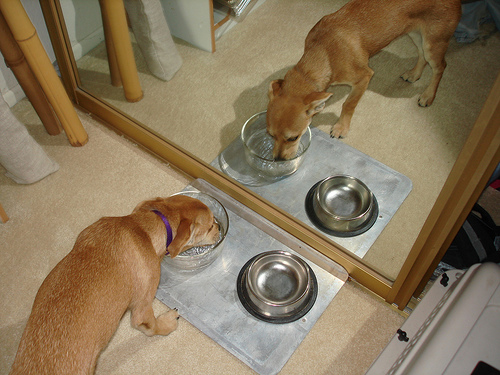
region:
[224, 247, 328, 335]
A metal water bowl with a rubber base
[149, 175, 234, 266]
A dog with his head in a glass bowl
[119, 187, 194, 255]
A purple collar around a dog's neck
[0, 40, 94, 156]
Bamboo propped in the corner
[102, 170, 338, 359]
A protective matt covering the carpet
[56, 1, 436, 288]
A large mirror against the wall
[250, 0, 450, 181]
The dog's reflection in the mirror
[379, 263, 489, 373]
A crate on the floor next to the mirror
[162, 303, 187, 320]
The dog's claws resting on the mat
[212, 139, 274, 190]
Light shining through the glass bowl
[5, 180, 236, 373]
a dog drinking water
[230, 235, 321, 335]
a silver food bowl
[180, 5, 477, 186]
the dog's reflection in the mirror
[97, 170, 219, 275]
the dog is wearing a purple collar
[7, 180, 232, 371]
the dog is brown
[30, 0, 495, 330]
the mirror's frame is brown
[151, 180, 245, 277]
the water bowl is clear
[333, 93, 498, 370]
the dog kennel is beside the mirror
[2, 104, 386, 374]
the carpet is tan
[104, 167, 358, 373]
the food dishes are on a mat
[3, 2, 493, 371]
dog eating in front of mirror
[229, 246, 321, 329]
a stainless steel dog bowl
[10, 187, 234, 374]
a yellow dog drinking water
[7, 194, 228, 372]
a dog with a purple collar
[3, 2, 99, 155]
a set of bamboo poles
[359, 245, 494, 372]
a white dog kennel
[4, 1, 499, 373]
a dog drinks while its reflection shows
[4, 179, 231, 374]
a dog drinks water from a glass bowl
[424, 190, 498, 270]
a black travel bag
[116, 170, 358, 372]
a rubber mat with dog bowls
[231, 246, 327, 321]
the food bowl is empty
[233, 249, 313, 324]
the food bowl is stainless steel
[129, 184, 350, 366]
the bowls are on a mat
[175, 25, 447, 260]
the mirror causes a reflection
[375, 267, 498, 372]
a carrier beside the mirror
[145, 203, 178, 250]
the dog collar is purple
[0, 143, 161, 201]
the carpet is light in colore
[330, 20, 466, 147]
you can see three legs in the mirror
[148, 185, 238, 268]
the water bowl is glass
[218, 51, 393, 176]
reflection of the dog eating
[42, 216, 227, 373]
the dog that is eating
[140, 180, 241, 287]
the dog drinking water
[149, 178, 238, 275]
a bucket of water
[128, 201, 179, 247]
a purple collar of the dog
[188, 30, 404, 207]
a nice mirror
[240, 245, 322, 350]
an empty food bowl for the dog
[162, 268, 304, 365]
the mat where the dog is eating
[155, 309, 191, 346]
the dogs paws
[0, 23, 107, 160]
a wooden pillar in the corner